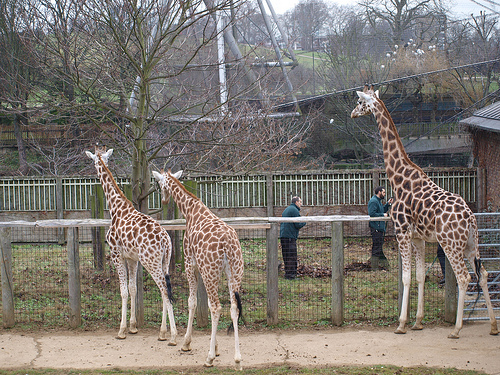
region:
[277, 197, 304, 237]
Man in green jacket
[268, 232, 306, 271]
Man in black pants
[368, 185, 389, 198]
Man with black hair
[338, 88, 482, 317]
Giraffe standing next to fence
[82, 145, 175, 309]
Giraffe looking over fence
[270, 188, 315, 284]
Person raking leaves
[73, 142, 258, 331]
Giraffe standing side by side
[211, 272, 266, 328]
Giraffe with black tail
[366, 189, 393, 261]
Person holding a rack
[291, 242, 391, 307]
Leaves on the ground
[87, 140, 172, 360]
this is a giraffe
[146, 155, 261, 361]
this is a giraffe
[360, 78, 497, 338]
this is a giraffe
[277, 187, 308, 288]
this is a person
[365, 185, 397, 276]
this is a person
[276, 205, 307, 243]
that is a green jack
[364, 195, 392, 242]
that is a green jack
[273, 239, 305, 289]
that is a black trouser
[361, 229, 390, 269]
that is a black trouser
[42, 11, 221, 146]
that is a tree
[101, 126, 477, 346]
Three giraffes in the zoo.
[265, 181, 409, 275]
Two attendants behind the fence.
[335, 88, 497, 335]
The giraffe is looking at the men.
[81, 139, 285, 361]
Two small giraffes next to each other.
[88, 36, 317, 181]
Trees and branches behind the fence.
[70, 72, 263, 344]
The giraffe is white and brown.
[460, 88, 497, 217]
A building next to the fence.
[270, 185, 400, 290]
Two men standing up.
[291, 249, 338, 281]
Brown leaves on the ground.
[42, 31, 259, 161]
The trees has no leaves.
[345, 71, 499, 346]
giraffe in a zoo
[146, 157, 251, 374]
giraffe in a zoo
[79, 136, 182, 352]
giraffe in a zoo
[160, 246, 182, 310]
black tail of a giraffe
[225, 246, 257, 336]
black tail of a giraffe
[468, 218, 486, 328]
black tail of a giraffe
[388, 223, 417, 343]
front leg of a giraffe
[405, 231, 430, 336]
front leg of a giraffe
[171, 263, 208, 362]
front leg of a giraffe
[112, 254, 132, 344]
front leg of a giraffe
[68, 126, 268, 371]
Two giraffes by a fence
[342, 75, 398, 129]
The head of a giraffe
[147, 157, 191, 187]
The ears of a giraffe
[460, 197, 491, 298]
The tail of a giraffe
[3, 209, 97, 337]
A wooden fence with mesh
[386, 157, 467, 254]
The pattern of a giraffe's coat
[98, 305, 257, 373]
The feet of two giraffes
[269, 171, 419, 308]
Two animal keepers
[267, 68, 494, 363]
A giraffe in a zoo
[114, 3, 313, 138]
A metal tower